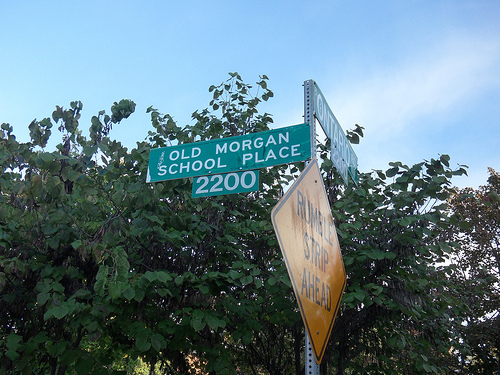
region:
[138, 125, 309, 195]
a green and white street sign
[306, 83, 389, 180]
a green and white street sign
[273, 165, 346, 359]
a yellow caution sign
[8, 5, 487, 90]
a mostly clear blue sky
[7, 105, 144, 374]
the green foliage of small deciduous trees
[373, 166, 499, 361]
the green foliage of small deciduous trees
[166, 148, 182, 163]
the letter O on a street sign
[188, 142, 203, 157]
the letter D on a street sign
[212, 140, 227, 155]
the letter M on a street sign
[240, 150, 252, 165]
the letter P on a street sign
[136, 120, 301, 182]
street sign on metal pole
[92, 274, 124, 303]
green leaves on tree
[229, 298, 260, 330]
green leaves on tree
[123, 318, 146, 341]
green leaves on tree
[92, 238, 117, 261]
green leaves on tree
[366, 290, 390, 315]
green leaves on tree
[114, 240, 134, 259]
green leaves on tree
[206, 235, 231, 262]
green leaves on tree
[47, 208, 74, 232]
green leaves on tree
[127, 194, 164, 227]
green leaves on tree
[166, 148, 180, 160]
the letter O on a sign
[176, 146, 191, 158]
the letter L on a sign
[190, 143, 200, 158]
the letter D on a sign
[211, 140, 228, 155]
the letter M on a sign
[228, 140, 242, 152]
the letter O on a sign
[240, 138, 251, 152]
the letter R on a sign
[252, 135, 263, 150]
the letter G on a sign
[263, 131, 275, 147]
the letter A on a sign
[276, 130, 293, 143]
the letter N on a sign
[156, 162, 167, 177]
the letter S on a sign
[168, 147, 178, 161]
the letter O on a sign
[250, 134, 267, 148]
the letter G on a sign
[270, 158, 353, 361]
a yellow caution sign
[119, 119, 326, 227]
the street sign is green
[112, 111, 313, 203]
the street sign is green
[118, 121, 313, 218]
the street sign is green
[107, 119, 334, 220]
the street sign is green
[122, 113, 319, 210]
the street sign is green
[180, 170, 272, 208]
the number is 2200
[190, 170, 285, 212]
the number is 2200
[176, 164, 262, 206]
the number is 2200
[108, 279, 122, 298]
A green leaf on a plant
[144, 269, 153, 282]
A green leaf on a plant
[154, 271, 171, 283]
A green leaf on a plant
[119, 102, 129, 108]
A green leaf on a plant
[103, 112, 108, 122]
A green leaf on a plant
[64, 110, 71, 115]
A green leaf on a plant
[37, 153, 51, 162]
A green leaf on a plant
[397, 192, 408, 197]
A green leaf on a plant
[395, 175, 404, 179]
A green leaf on a plant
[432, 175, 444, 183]
A green leaf on a plant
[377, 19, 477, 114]
Large body of blue skies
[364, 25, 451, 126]
Large body of blue skies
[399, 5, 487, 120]
Large body of blue skies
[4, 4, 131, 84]
Large body of blue skies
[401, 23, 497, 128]
Large body of blue skies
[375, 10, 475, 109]
Large body of blue skies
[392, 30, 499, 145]
Large body of blue skies